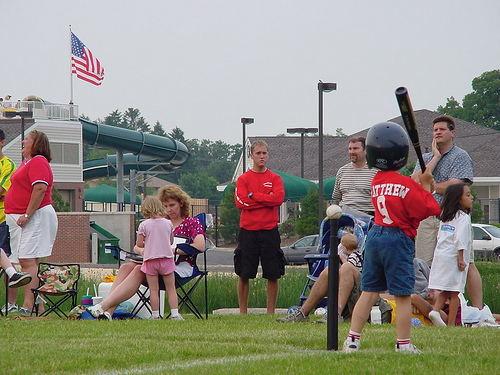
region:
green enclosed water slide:
[38, 87, 190, 202]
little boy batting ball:
[331, 77, 438, 374]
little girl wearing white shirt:
[428, 177, 486, 331]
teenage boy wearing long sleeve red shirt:
[225, 138, 302, 319]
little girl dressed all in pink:
[128, 189, 191, 328]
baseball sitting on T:
[297, 185, 362, 370]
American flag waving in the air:
[57, 19, 116, 133]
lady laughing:
[3, 123, 67, 182]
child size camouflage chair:
[20, 252, 95, 335]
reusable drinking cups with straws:
[79, 277, 107, 321]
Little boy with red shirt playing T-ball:
[303, 79, 451, 362]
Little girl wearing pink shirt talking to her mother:
[108, 177, 213, 322]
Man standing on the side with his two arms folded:
[215, 111, 305, 315]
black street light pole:
[305, 71, 340, 231]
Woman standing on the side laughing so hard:
[0, 105, 45, 315]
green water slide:
[0, 75, 208, 190]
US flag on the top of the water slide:
[42, 20, 120, 120]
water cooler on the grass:
[77, 268, 117, 318]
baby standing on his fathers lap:
[335, 227, 370, 278]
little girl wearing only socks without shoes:
[428, 171, 474, 321]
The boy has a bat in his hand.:
[343, 88, 470, 349]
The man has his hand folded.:
[222, 120, 290, 292]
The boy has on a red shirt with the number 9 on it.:
[353, 152, 429, 238]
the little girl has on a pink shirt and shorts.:
[123, 197, 180, 320]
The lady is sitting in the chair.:
[136, 178, 221, 320]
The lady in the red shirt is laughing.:
[13, 125, 65, 310]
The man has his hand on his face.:
[423, 106, 476, 195]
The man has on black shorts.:
[228, 216, 295, 307]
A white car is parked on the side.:
[472, 217, 498, 266]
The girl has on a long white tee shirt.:
[440, 206, 478, 315]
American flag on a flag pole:
[69, 27, 102, 86]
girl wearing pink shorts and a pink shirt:
[143, 197, 173, 316]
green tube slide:
[85, 119, 180, 172]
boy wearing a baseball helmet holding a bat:
[369, 82, 421, 357]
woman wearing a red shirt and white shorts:
[13, 129, 51, 259]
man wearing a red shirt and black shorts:
[238, 143, 282, 310]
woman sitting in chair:
[176, 185, 209, 287]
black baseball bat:
[396, 85, 426, 170]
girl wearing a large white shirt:
[440, 186, 464, 325]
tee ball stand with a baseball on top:
[325, 202, 341, 347]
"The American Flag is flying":
[46, 26, 140, 109]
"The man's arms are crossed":
[219, 138, 295, 316]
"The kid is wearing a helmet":
[360, 88, 444, 310]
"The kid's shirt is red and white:
[356, 92, 463, 282]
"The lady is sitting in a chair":
[138, 171, 230, 339]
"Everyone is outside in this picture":
[3, 96, 495, 371]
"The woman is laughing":
[3, 108, 70, 327]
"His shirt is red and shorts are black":
[211, 135, 304, 319]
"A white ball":
[316, 196, 362, 235]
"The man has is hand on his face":
[416, 81, 488, 372]